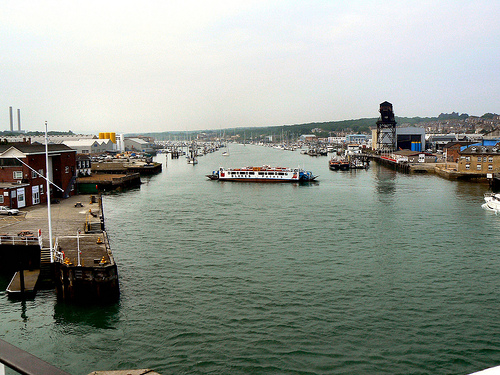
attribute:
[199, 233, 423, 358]
water — clear, Wavy greenish blue, body , green, waves, calm 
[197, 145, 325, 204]
boat — white, ferry, blue , red, large , long, wooden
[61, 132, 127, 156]
roof — white, black , slanted 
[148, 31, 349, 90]
sky — clear, Gray , light blue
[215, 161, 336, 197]
ferry — white 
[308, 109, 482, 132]
hill — small 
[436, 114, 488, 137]
tress — Green 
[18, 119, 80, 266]
pole —  tall white  , tall, white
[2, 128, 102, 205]
building — brown , white , small , large , round , yellow , rusty, red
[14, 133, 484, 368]
water — body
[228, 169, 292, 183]
windows — Many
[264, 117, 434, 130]
hillside — small 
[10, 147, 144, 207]
building — brown 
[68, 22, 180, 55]
clouds — white 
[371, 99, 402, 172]
tower — white , brown 